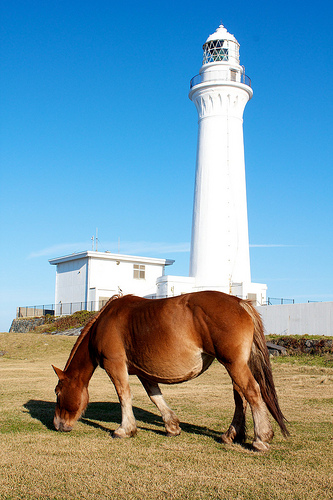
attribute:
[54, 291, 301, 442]
horse — eating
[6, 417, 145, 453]
grass — green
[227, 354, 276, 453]
leg — horse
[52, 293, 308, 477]
horse — brown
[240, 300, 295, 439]
horse tail — large brown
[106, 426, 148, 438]
horse hoof — large round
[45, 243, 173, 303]
building — large white square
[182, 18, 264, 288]
lighthouse — tall white large 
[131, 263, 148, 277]
window — small square glass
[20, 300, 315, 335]
fence — large wide metal 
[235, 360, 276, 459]
horse leg — large long 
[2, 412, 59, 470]
grassy area — large wide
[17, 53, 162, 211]
sky — large open blue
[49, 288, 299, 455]
horse — brown, large brown hairy , she, small, grazing, beautiful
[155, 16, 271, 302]
lighthouse — tall, white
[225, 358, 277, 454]
leg — rear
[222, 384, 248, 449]
leg — rear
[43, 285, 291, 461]
horse — brown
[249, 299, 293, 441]
tail — long, brown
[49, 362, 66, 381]
ear — brown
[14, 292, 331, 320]
fence — metal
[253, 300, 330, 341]
wall — large, smooth, gray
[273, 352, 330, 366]
vegetation — dark green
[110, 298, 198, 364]
fur — brown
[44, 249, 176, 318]
building — large, white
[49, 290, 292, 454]
she — a bay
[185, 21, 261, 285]
light house — bright white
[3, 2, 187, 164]
sky — perfectly blue, brilliant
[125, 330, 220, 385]
stomach — fat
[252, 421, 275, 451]
hoof — back left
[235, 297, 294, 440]
tail — long, horse's